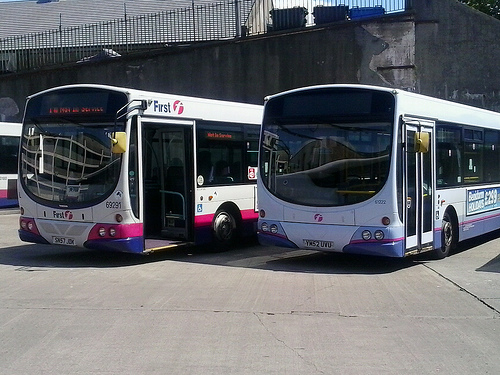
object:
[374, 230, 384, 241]
headlight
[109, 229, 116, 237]
headlight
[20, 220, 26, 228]
headlight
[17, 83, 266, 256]
bus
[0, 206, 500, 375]
ground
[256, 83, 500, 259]
bus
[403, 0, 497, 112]
wall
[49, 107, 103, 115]
destination sign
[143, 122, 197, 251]
bus door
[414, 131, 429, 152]
side mirror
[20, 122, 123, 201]
windows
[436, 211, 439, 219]
small sign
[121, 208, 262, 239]
stripe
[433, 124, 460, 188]
window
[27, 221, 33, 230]
head light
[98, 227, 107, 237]
head light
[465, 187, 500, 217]
sign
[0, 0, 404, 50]
railing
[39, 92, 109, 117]
board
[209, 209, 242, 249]
tire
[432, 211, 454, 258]
tire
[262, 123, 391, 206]
window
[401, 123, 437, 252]
door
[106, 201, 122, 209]
numbers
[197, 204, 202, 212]
handicap sign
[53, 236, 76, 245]
number plate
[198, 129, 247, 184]
window